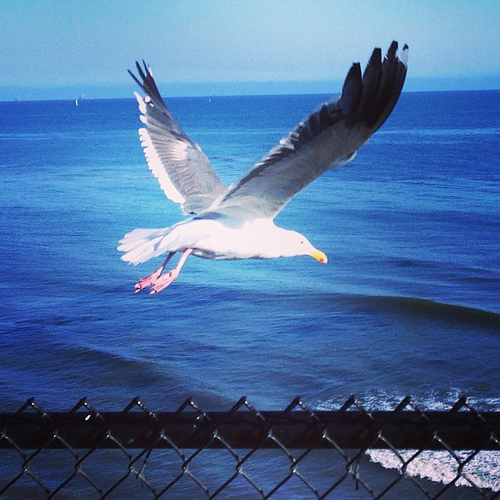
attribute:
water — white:
[0, 88, 497, 495]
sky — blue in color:
[3, 1, 498, 87]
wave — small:
[337, 279, 496, 338]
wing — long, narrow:
[209, 40, 416, 231]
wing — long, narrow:
[125, 55, 222, 215]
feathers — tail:
[116, 222, 167, 266]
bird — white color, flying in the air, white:
[116, 37, 410, 295]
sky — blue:
[2, 1, 499, 114]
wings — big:
[118, 47, 440, 213]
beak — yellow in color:
[310, 250, 332, 268]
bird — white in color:
[74, 37, 426, 374]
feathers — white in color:
[211, 190, 279, 256]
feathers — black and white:
[91, 53, 421, 206]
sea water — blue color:
[24, 138, 111, 239]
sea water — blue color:
[376, 177, 453, 294]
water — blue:
[367, 182, 498, 277]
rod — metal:
[0, 409, 182, 444]